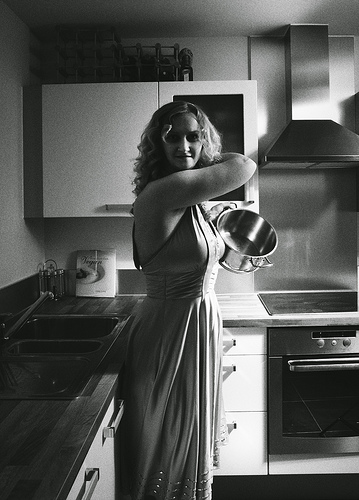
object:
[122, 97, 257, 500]
lady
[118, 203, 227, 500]
dress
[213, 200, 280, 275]
pot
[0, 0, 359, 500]
kitchen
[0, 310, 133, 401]
sink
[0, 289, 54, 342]
faucet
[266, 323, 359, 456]
oven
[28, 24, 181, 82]
rack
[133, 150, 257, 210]
arm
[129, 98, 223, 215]
hair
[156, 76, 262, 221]
cabinets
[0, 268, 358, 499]
counter top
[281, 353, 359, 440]
window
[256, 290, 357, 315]
stove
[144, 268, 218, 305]
mid waist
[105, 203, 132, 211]
handle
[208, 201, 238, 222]
hand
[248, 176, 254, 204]
handle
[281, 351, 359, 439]
door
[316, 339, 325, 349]
knob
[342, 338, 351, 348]
knob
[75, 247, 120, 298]
cook book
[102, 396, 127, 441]
handle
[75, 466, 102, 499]
handle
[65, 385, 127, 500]
cabinet